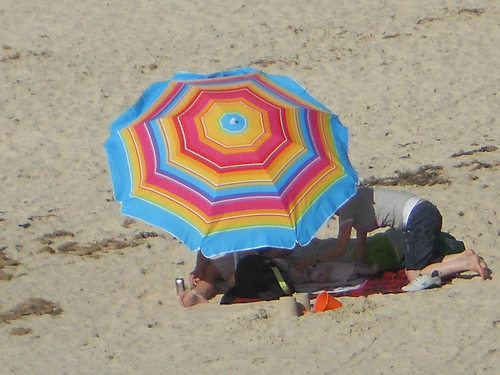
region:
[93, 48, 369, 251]
a multicolored umbrella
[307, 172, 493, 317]
someone on all fours on the ground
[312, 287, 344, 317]
a orange bucket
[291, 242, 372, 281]
a small baby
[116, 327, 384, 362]
tracks in the sand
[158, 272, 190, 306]
a coca cola can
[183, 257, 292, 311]
a black bag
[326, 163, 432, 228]
someone wearing a grey shirt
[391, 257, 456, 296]
a white tennis shoe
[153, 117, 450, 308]
three people under a umbrella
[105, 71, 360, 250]
a pink orange light blue dark blue beach umbrella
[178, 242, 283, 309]
a person on the sand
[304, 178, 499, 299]
a person on the sand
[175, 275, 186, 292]
the silver can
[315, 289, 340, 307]
the orange plastic bucket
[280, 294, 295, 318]
a small sandcastle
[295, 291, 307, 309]
a small sandcastle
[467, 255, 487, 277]
the foot of the person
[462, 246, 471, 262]
the foot of the person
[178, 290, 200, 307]
the foot of the person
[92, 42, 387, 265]
a muliticolored umbella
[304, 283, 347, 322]
a orange bucket on the beach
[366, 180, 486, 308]
a person with no shoes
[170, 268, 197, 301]
a coke can in the sand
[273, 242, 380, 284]
a baby laying on a blanket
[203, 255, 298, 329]
a black bag with a green handle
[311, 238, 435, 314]
a red blanket on the beach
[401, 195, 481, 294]
a person wearing blue jean shorts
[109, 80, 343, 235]
colorful rainbow beach umbrella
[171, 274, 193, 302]
silver and red beer can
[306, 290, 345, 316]
orange pail for sand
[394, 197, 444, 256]
black men's shorts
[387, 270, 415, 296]
red and black plaid blanket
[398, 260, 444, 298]
white and blue sneaker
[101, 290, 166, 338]
tan beach sand with brown specs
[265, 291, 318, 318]
two towers of sand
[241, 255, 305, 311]
yellow and black bag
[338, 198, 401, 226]
gray and white t shirt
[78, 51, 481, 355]
people under a beach umbrella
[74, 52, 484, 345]
people under a large beach umbrella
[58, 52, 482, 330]
people under a bright beach umbrella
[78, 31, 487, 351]
people under a big beach umbrella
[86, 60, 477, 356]
people under a colorful beach umbrella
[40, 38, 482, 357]
people under a huge beach umbrella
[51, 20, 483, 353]
some people under beach umbrella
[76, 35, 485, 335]
some people under bright beach umbrella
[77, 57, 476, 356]
some people under colorful beach umbrella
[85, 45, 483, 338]
some people under nice beach umbrella